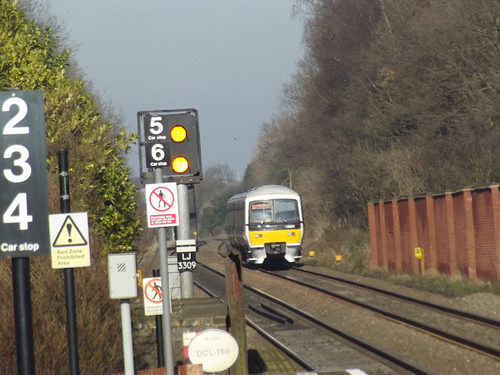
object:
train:
[224, 182, 304, 271]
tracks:
[188, 238, 499, 375]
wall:
[366, 183, 499, 290]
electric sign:
[250, 203, 272, 211]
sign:
[146, 182, 179, 230]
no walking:
[150, 186, 175, 211]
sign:
[46, 211, 91, 272]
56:
[148, 116, 166, 161]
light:
[170, 127, 187, 143]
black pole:
[55, 150, 81, 374]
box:
[108, 252, 139, 301]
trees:
[0, 1, 499, 374]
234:
[0, 90, 50, 259]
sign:
[1, 90, 52, 258]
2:
[2, 98, 30, 137]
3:
[3, 144, 31, 183]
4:
[3, 193, 33, 232]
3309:
[177, 261, 197, 270]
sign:
[176, 253, 198, 271]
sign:
[188, 328, 239, 372]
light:
[173, 156, 189, 173]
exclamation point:
[66, 222, 76, 244]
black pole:
[11, 257, 37, 374]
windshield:
[249, 199, 302, 231]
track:
[189, 239, 434, 375]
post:
[137, 109, 202, 299]